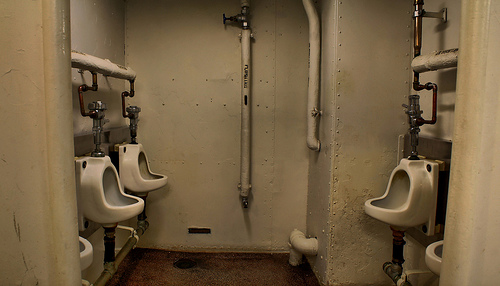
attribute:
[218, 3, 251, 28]
handle — faucet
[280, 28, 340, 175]
pipe — WHITE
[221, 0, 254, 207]
pipe — white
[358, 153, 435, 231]
urinal — white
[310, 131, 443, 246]
urinal — WHITE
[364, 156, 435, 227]
urinal — vacant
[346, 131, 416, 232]
urinal — white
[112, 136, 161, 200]
urinal — white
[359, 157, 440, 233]
urinal — porcelain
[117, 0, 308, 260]
wall — grey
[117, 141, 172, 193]
urinal — vacant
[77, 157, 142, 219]
urinal — porcelain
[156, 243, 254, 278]
floor — dark, dirty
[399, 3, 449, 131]
pipe — METAL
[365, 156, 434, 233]
urinal — white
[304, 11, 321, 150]
pipe — white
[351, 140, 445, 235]
urinal — porcelain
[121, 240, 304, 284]
floor — brown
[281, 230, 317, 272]
pipe — WHITE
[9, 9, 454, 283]
room — bleak